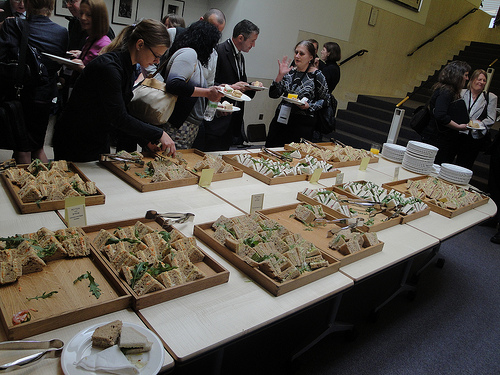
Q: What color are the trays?
A: Tan.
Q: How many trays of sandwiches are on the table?
A: Twelve.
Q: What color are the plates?
A: White.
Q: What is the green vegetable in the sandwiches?
A: Lettuce.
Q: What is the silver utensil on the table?
A: Tongs.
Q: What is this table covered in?
A: Boxes of sandwiches.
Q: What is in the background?
A: A flight of stairs.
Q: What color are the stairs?
A: Gray.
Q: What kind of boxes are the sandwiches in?
A: Wooden boxes.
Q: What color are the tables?
A: White.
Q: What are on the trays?
A: Sandwiches.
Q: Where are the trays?
A: On the tables.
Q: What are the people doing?
A: Eating.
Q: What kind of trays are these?
A: Wood.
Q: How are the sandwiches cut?
A: Triangles.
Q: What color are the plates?
A: White.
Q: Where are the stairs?
A: In the back.